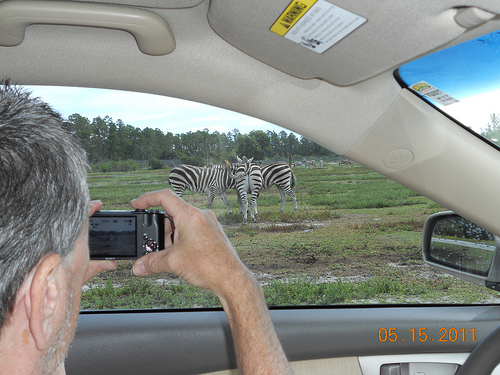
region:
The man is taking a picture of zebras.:
[0, 7, 495, 367]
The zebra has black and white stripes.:
[180, 170, 220, 180]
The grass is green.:
[335, 185, 395, 195]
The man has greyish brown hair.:
[0, 81, 90, 316]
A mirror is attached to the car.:
[410, 192, 497, 289]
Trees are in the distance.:
[75, 110, 260, 160]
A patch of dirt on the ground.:
[305, 261, 355, 272]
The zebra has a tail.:
[215, 150, 260, 180]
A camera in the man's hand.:
[45, 175, 225, 300]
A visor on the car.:
[201, 0, 497, 110]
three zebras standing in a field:
[143, 128, 355, 289]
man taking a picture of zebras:
[1, 110, 240, 367]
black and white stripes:
[174, 156, 265, 203]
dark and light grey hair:
[0, 81, 155, 301]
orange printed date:
[364, 314, 490, 349]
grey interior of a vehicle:
[21, 33, 487, 365]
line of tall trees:
[53, 100, 357, 197]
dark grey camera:
[60, 186, 200, 260]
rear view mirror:
[414, 197, 495, 293]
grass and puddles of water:
[249, 220, 456, 312]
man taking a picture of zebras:
[42, 166, 210, 275]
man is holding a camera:
[59, 197, 212, 262]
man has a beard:
[38, 270, 116, 366]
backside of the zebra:
[223, 144, 277, 217]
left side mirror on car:
[371, 177, 496, 267]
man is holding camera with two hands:
[58, 161, 196, 270]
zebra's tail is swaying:
[201, 147, 277, 210]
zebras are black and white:
[182, 138, 325, 206]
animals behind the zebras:
[255, 149, 363, 178]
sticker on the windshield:
[396, 65, 478, 125]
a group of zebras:
[158, 143, 324, 262]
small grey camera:
[70, 176, 192, 301]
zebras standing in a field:
[146, 131, 448, 328]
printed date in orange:
[358, 310, 483, 353]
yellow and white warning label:
[235, 0, 373, 62]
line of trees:
[63, 93, 385, 194]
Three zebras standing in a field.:
[153, 146, 313, 224]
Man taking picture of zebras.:
[3, 118, 180, 373]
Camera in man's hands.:
[86, 188, 193, 284]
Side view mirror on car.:
[413, 208, 498, 288]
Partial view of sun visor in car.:
[206, 1, 492, 86]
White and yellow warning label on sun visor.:
[261, 1, 366, 65]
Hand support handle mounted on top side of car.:
[3, 1, 199, 69]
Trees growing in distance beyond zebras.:
[81, 113, 323, 164]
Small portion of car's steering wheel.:
[451, 324, 499, 374]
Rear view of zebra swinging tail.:
[223, 155, 271, 224]